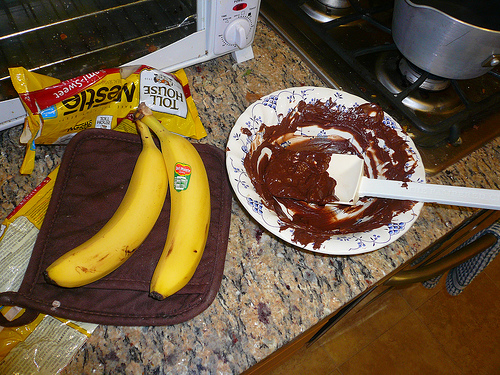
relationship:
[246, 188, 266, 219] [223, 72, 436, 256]
pattern on plate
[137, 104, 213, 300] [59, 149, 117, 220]
banana laying mitt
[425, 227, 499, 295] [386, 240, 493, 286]
towel on bar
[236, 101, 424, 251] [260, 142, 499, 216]
chocolate on spatula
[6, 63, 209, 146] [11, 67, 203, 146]
chcolate in bag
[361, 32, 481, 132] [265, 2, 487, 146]
burner on stove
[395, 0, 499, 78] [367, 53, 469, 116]
metal pan on burner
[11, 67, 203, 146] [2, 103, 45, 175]
bag with top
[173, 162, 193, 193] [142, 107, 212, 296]
banana label on banana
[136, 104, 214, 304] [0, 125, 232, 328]
banana on mitt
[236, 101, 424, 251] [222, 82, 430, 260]
chocolate on paper plate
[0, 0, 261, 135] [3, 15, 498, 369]
microwave on countertop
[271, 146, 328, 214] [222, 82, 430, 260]
chocolate on paper plate